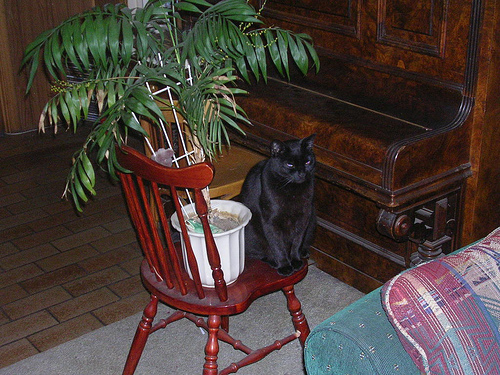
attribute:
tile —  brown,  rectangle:
[47, 220, 112, 253]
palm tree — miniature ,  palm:
[28, 10, 335, 240]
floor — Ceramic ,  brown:
[0, 171, 125, 359]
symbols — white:
[411, 278, 453, 339]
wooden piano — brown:
[212, 17, 440, 244]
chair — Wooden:
[96, 111, 309, 373]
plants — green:
[100, 22, 293, 159]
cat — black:
[210, 121, 351, 286]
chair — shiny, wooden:
[111, 120, 310, 374]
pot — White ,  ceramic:
[178, 181, 311, 285]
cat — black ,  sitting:
[238, 132, 318, 275]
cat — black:
[243, 134, 333, 281]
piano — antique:
[233, 12, 498, 303]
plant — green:
[16, 1, 324, 290]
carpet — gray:
[11, 265, 371, 370]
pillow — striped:
[383, 225, 497, 367]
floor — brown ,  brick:
[0, 120, 153, 367]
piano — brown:
[182, 27, 495, 177]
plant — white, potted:
[53, 1, 333, 283]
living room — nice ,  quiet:
[3, 3, 499, 373]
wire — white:
[129, 107, 161, 158]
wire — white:
[135, 60, 195, 205]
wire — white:
[156, 51, 194, 167]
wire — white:
[184, 57, 195, 89]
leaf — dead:
[94, 84, 104, 113]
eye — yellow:
[284, 157, 295, 168]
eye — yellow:
[304, 158, 312, 168]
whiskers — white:
[284, 171, 315, 182]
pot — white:
[168, 194, 254, 290]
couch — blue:
[302, 222, 499, 372]